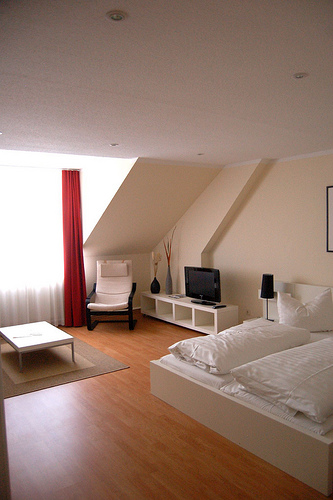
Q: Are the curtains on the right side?
A: No, the curtains are on the left of the image.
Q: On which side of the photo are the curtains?
A: The curtains are on the left of the image.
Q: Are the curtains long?
A: Yes, the curtains are long.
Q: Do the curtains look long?
A: Yes, the curtains are long.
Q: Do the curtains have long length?
A: Yes, the curtains are long.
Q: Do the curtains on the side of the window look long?
A: Yes, the curtains are long.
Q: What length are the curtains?
A: The curtains are long.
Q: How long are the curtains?
A: The curtains are long.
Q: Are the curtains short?
A: No, the curtains are long.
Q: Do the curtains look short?
A: No, the curtains are long.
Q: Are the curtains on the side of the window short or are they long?
A: The curtains are long.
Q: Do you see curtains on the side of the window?
A: Yes, there are curtains on the side of the window.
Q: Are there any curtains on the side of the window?
A: Yes, there are curtains on the side of the window.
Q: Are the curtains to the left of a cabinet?
A: No, the curtains are to the left of the vase.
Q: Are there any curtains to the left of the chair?
A: Yes, there are curtains to the left of the chair.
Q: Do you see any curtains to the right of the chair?
A: No, the curtains are to the left of the chair.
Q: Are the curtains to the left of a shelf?
A: No, the curtains are to the left of a chair.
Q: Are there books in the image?
A: No, there are no books.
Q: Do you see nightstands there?
A: Yes, there is a nightstand.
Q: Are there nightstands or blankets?
A: Yes, there is a nightstand.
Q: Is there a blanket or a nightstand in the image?
A: Yes, there is a nightstand.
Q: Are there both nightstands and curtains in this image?
A: Yes, there are both a nightstand and a curtain.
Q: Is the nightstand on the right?
A: Yes, the nightstand is on the right of the image.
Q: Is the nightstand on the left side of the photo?
A: No, the nightstand is on the right of the image.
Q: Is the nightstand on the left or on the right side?
A: The nightstand is on the right of the image.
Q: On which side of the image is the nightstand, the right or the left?
A: The nightstand is on the right of the image.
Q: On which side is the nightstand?
A: The nightstand is on the right of the image.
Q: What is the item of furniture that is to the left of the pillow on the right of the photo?
A: The piece of furniture is a nightstand.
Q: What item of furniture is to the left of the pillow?
A: The piece of furniture is a nightstand.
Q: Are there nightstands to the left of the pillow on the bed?
A: Yes, there is a nightstand to the left of the pillow.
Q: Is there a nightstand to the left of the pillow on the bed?
A: Yes, there is a nightstand to the left of the pillow.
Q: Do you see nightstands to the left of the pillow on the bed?
A: Yes, there is a nightstand to the left of the pillow.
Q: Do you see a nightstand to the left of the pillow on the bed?
A: Yes, there is a nightstand to the left of the pillow.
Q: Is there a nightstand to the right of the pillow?
A: No, the nightstand is to the left of the pillow.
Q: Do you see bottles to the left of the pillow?
A: No, there is a nightstand to the left of the pillow.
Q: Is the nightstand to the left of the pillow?
A: Yes, the nightstand is to the left of the pillow.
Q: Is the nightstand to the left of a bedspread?
A: No, the nightstand is to the left of the pillow.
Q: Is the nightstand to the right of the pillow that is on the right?
A: No, the nightstand is to the left of the pillow.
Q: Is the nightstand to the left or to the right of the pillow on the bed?
A: The nightstand is to the left of the pillow.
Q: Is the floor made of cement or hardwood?
A: The floor is made of hardwood.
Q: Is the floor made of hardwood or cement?
A: The floor is made of hardwood.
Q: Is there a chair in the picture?
A: Yes, there is a chair.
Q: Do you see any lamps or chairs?
A: Yes, there is a chair.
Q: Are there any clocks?
A: No, there are no clocks.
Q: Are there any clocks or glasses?
A: No, there are no clocks or glasses.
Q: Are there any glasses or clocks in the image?
A: No, there are no clocks or glasses.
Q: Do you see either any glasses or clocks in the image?
A: No, there are no clocks or glasses.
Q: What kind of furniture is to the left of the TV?
A: The piece of furniture is a chair.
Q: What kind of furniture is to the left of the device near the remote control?
A: The piece of furniture is a chair.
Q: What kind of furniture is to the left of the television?
A: The piece of furniture is a chair.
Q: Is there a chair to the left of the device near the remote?
A: Yes, there is a chair to the left of the television.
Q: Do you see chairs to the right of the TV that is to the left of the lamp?
A: No, the chair is to the left of the television.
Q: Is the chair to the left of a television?
A: Yes, the chair is to the left of a television.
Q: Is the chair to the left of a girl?
A: No, the chair is to the left of a television.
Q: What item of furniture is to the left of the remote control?
A: The piece of furniture is a chair.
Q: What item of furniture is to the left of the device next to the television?
A: The piece of furniture is a chair.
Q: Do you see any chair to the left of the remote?
A: Yes, there is a chair to the left of the remote.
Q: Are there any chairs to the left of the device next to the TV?
A: Yes, there is a chair to the left of the remote.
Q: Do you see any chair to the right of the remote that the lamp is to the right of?
A: No, the chair is to the left of the remote.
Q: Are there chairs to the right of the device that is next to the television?
A: No, the chair is to the left of the remote.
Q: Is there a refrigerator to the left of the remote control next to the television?
A: No, there is a chair to the left of the remote.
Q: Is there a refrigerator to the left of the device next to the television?
A: No, there is a chair to the left of the remote.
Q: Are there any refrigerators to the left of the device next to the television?
A: No, there is a chair to the left of the remote.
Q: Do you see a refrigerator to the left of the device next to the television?
A: No, there is a chair to the left of the remote.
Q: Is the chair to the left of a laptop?
A: No, the chair is to the left of the remote.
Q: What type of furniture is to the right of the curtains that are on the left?
A: The piece of furniture is a chair.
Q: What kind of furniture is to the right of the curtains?
A: The piece of furniture is a chair.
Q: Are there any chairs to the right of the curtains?
A: Yes, there is a chair to the right of the curtains.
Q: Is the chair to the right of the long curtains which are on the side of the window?
A: Yes, the chair is to the right of the curtains.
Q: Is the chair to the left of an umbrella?
A: No, the chair is to the left of the vase.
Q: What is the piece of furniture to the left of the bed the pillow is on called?
A: The piece of furniture is a chair.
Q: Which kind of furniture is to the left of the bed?
A: The piece of furniture is a chair.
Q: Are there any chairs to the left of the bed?
A: Yes, there is a chair to the left of the bed.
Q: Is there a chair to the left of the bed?
A: Yes, there is a chair to the left of the bed.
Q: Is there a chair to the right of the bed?
A: No, the chair is to the left of the bed.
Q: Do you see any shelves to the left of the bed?
A: No, there is a chair to the left of the bed.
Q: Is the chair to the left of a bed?
A: Yes, the chair is to the left of a bed.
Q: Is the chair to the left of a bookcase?
A: No, the chair is to the left of a bed.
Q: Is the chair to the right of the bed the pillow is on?
A: No, the chair is to the left of the bed.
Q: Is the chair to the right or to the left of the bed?
A: The chair is to the left of the bed.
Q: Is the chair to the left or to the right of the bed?
A: The chair is to the left of the bed.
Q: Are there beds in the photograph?
A: Yes, there is a bed.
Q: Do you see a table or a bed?
A: Yes, there is a bed.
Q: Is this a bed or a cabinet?
A: This is a bed.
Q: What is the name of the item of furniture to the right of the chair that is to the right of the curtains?
A: The piece of furniture is a bed.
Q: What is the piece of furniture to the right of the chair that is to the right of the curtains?
A: The piece of furniture is a bed.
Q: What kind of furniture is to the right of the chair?
A: The piece of furniture is a bed.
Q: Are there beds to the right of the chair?
A: Yes, there is a bed to the right of the chair.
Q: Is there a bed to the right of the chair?
A: Yes, there is a bed to the right of the chair.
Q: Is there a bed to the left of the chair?
A: No, the bed is to the right of the chair.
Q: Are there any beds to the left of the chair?
A: No, the bed is to the right of the chair.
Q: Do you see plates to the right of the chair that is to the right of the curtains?
A: No, there is a bed to the right of the chair.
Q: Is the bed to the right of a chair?
A: Yes, the bed is to the right of a chair.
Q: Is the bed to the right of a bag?
A: No, the bed is to the right of a chair.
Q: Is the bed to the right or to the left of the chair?
A: The bed is to the right of the chair.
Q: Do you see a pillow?
A: Yes, there is a pillow.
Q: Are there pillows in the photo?
A: Yes, there is a pillow.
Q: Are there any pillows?
A: Yes, there is a pillow.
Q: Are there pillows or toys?
A: Yes, there is a pillow.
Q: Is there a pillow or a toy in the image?
A: Yes, there is a pillow.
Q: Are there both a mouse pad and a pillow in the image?
A: No, there is a pillow but no mouse pads.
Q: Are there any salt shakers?
A: No, there are no salt shakers.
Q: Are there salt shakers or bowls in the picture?
A: No, there are no salt shakers or bowls.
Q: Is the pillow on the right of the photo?
A: Yes, the pillow is on the right of the image.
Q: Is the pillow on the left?
A: No, the pillow is on the right of the image.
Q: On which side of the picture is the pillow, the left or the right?
A: The pillow is on the right of the image.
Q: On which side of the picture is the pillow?
A: The pillow is on the right of the image.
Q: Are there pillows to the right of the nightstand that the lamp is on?
A: Yes, there is a pillow to the right of the nightstand.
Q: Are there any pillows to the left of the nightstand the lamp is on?
A: No, the pillow is to the right of the nightstand.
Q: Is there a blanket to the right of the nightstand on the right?
A: No, there is a pillow to the right of the nightstand.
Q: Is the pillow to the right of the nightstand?
A: Yes, the pillow is to the right of the nightstand.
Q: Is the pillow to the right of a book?
A: No, the pillow is to the right of the nightstand.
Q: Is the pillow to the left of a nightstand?
A: No, the pillow is to the right of a nightstand.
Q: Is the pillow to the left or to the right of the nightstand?
A: The pillow is to the right of the nightstand.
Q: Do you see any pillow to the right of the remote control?
A: Yes, there is a pillow to the right of the remote control.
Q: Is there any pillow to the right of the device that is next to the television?
A: Yes, there is a pillow to the right of the remote control.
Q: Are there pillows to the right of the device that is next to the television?
A: Yes, there is a pillow to the right of the remote control.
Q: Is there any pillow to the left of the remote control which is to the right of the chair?
A: No, the pillow is to the right of the remote.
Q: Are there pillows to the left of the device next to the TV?
A: No, the pillow is to the right of the remote.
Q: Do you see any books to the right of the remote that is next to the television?
A: No, there is a pillow to the right of the remote control.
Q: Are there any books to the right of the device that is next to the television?
A: No, there is a pillow to the right of the remote control.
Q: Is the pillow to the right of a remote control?
A: Yes, the pillow is to the right of a remote control.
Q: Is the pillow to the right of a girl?
A: No, the pillow is to the right of a remote control.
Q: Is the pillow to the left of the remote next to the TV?
A: No, the pillow is to the right of the remote.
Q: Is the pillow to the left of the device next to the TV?
A: No, the pillow is to the right of the remote.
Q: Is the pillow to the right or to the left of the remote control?
A: The pillow is to the right of the remote control.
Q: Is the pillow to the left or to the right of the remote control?
A: The pillow is to the right of the remote control.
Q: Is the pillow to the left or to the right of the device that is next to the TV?
A: The pillow is to the right of the remote control.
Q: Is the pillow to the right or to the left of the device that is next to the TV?
A: The pillow is to the right of the remote control.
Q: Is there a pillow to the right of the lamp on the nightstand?
A: Yes, there is a pillow to the right of the lamp.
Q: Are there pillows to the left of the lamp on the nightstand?
A: No, the pillow is to the right of the lamp.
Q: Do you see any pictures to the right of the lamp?
A: No, there is a pillow to the right of the lamp.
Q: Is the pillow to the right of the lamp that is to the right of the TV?
A: Yes, the pillow is to the right of the lamp.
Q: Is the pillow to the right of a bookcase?
A: No, the pillow is to the right of the lamp.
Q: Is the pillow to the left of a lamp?
A: No, the pillow is to the right of a lamp.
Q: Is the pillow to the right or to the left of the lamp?
A: The pillow is to the right of the lamp.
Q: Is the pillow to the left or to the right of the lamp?
A: The pillow is to the right of the lamp.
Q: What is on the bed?
A: The pillow is on the bed.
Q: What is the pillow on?
A: The pillow is on the bed.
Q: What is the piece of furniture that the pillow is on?
A: The piece of furniture is a bed.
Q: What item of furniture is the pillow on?
A: The pillow is on the bed.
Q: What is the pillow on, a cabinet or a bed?
A: The pillow is on a bed.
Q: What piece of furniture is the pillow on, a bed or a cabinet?
A: The pillow is on a bed.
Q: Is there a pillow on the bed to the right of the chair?
A: Yes, there is a pillow on the bed.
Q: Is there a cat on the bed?
A: No, there is a pillow on the bed.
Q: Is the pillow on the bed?
A: Yes, the pillow is on the bed.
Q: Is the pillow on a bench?
A: No, the pillow is on the bed.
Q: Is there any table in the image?
A: Yes, there is a table.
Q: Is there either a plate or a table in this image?
A: Yes, there is a table.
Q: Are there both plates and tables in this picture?
A: No, there is a table but no plates.